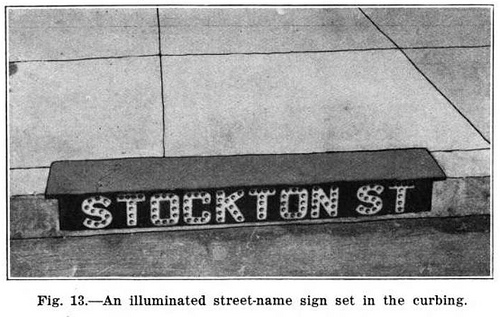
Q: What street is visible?
A: Stockton.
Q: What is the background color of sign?
A: Black.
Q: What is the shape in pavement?
A: Squares.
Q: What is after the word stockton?
A: St.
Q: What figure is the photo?
A: 13.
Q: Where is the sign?
A: In curbing.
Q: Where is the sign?
A: On the curb of the street.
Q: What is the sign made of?
A: Metal and lights.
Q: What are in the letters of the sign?
A: Lights.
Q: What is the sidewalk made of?
A: Slabs.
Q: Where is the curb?
A: At the edge of the street?.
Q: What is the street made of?
A: Asphalt.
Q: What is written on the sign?
A: Stockton St.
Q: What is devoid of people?
A: The sidewalk.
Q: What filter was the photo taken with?
A: Black and white.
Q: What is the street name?
A: Stockton St.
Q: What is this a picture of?
A: Sidewalk and curb.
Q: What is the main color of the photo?
A: Black and white.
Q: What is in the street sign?
A: Light bulbs.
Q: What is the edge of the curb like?
A: Squared.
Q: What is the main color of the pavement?
A: Gray.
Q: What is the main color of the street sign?
A: Black.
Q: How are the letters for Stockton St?
A: Uppercase.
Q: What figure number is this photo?
A: 13.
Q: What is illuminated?
A: Street sign set in curbing.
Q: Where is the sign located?
A: In the curb on the street.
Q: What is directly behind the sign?
A: Sidewalk.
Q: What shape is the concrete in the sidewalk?
A: Square.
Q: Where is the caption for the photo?
A: Beneath the photo.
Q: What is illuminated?
A: The lettering.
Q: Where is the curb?
A: At the edge of the sidewalk.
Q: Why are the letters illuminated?
A: So they can be seen at night.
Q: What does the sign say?
A: Stockton St.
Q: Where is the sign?
A: In the curb.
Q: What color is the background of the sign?
A: Black.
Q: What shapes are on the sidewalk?
A: Squares.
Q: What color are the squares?
A: Grey.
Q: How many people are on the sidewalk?
A: None.